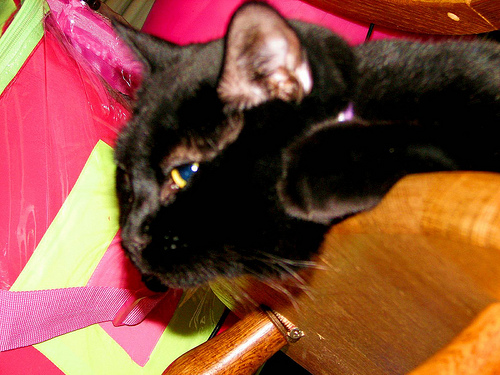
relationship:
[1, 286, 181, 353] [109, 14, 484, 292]
leash near cat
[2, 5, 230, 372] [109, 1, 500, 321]
pattern near cat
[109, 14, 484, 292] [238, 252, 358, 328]
cat has whiskers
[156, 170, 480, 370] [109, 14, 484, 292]
chair under cat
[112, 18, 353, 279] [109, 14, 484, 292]
head of cat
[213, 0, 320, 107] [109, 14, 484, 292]
ear of cat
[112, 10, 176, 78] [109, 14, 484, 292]
ear of cat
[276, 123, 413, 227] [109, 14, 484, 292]
paw of cat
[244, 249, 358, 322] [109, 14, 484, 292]
whisker of cat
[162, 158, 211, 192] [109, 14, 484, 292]
eye of cat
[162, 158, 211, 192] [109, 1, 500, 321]
eye of cat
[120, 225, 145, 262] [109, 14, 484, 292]
nose of cat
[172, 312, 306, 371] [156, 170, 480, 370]
leg of chair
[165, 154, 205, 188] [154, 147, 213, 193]
reflection in eye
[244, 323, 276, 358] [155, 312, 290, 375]
reflection on leg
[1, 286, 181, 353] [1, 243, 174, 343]
leash of leash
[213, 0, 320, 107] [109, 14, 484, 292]
ear of a cat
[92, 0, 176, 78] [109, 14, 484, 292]
ear of a cat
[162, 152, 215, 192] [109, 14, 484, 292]
eye of a cat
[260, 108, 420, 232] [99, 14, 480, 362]
paw of a cat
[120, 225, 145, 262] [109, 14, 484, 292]
nose of a cat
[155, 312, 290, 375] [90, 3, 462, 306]
leg under cat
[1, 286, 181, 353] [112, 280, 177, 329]
leash with buckle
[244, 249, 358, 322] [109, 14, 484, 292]
whisker of a cat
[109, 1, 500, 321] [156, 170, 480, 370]
cat laying on a chair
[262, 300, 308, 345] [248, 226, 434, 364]
screw on bottom chair